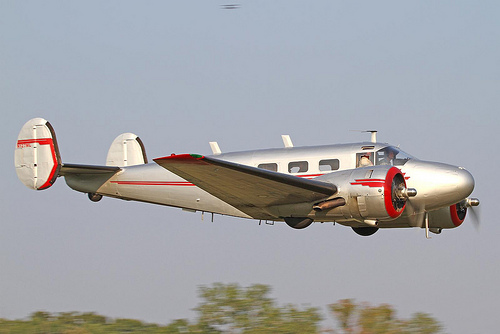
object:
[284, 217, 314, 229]
wheel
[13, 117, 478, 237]
airplaine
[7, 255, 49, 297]
cloud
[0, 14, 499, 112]
air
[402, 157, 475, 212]
nose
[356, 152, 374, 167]
man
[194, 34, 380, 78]
sky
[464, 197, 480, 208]
engine propeller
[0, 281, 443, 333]
trees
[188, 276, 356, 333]
tops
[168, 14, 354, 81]
clouds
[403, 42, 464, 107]
white clouds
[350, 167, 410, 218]
red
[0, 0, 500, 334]
blue skies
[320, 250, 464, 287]
clouds sky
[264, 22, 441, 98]
clouds sky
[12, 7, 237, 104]
clouds sky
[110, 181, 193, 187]
red stripe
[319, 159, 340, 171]
window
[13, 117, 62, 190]
tail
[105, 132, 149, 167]
tail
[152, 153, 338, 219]
wing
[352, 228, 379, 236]
wheel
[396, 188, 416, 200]
propellor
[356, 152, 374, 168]
window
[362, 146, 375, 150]
window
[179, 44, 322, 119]
clouds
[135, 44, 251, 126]
clouds